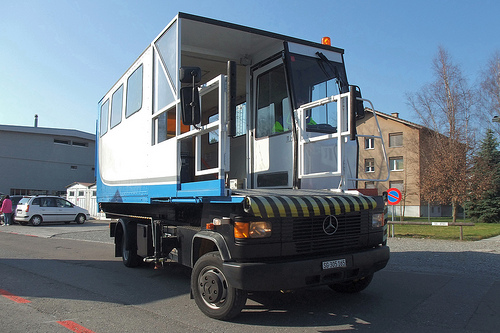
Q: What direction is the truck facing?
A: Right.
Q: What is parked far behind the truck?
A: A white van.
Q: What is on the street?
A: A truck.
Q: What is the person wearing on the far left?
A: A pink coat.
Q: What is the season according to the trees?
A: Fall.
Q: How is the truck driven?
A: A steering wheel.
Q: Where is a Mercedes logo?
A: On front of the truck.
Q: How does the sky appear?
A: Clear and blue.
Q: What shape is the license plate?
A: Rectangular.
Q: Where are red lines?
A: On the pavement.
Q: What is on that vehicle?
A: A custom built top.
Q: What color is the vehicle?
A: Blue, white and black.